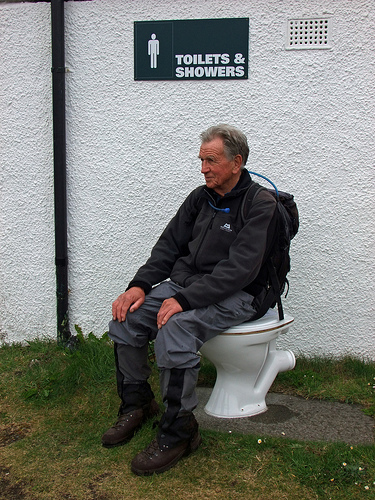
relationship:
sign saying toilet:
[130, 15, 251, 84] [174, 52, 228, 66]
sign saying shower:
[130, 15, 251, 84] [173, 63, 245, 78]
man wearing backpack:
[98, 123, 302, 478] [180, 172, 305, 322]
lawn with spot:
[5, 323, 362, 451] [160, 375, 352, 450]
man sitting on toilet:
[98, 123, 302, 478] [198, 303, 300, 419]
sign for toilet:
[130, 15, 251, 84] [198, 303, 300, 419]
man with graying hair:
[98, 123, 302, 478] [187, 121, 260, 167]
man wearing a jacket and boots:
[98, 123, 302, 478] [101, 399, 202, 476]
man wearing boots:
[98, 123, 302, 478] [91, 386, 204, 472]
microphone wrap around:
[194, 169, 277, 205] [202, 167, 281, 236]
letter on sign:
[183, 54, 193, 66] [130, 15, 251, 84]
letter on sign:
[198, 54, 205, 64] [130, 15, 251, 84]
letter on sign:
[213, 53, 221, 65] [130, 15, 251, 84]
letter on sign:
[175, 66, 184, 78] [130, 15, 251, 84]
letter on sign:
[194, 66, 204, 77] [130, 15, 251, 84]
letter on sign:
[174, 53, 183, 65] [130, 15, 251, 84]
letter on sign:
[183, 53, 192, 65] [130, 15, 251, 84]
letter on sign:
[192, 53, 197, 64] [130, 15, 251, 84]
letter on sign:
[197, 53, 205, 65] [130, 15, 251, 84]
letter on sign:
[205, 53, 213, 63] [130, 15, 251, 84]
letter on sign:
[219, 52, 229, 63] [130, 15, 251, 84]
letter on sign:
[175, 66, 183, 78] [130, 15, 251, 84]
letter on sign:
[184, 66, 194, 77] [130, 15, 251, 84]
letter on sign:
[193, 66, 203, 77] [130, 15, 251, 84]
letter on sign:
[216, 66, 225, 76] [130, 15, 251, 84]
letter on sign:
[225, 66, 234, 76] [130, 15, 251, 84]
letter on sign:
[235, 64, 243, 76] [130, 15, 251, 84]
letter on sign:
[184, 65, 193, 78] [133, 17, 249, 79]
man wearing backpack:
[98, 123, 302, 478] [257, 180, 300, 328]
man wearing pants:
[98, 123, 296, 498] [108, 278, 254, 411]